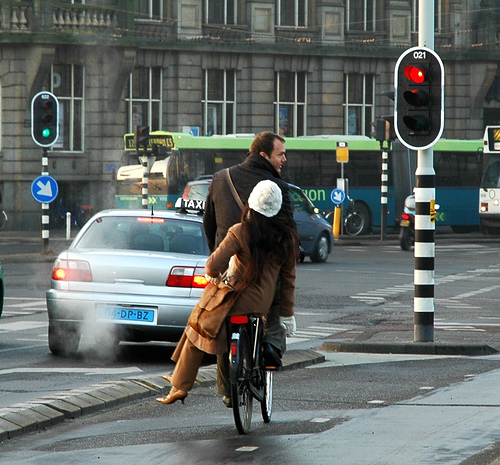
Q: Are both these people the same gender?
A: No, they are both male and female.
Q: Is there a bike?
A: Yes, there is a bike.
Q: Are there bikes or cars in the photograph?
A: Yes, there is a bike.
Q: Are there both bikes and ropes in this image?
A: No, there is a bike but no ropes.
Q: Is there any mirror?
A: No, there are no mirrors.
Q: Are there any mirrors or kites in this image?
A: No, there are no mirrors or kites.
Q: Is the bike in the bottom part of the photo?
A: Yes, the bike is in the bottom of the image.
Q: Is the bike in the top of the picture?
A: No, the bike is in the bottom of the image.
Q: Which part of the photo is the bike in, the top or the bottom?
A: The bike is in the bottom of the image.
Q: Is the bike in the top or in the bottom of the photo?
A: The bike is in the bottom of the image.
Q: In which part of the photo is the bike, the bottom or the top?
A: The bike is in the bottom of the image.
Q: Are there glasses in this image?
A: No, there are no glasses.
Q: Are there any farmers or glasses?
A: No, there are no glasses or farmers.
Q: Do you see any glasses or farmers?
A: No, there are no glasses or farmers.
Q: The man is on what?
A: The man is on the bike.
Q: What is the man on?
A: The man is on the bike.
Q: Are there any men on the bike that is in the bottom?
A: Yes, there is a man on the bike.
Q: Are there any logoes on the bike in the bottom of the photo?
A: No, there is a man on the bike.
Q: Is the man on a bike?
A: Yes, the man is on a bike.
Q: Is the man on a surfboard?
A: No, the man is on a bike.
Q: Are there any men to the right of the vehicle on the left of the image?
A: Yes, there is a man to the right of the car.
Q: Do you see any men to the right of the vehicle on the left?
A: Yes, there is a man to the right of the car.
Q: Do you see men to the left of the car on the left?
A: No, the man is to the right of the car.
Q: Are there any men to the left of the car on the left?
A: No, the man is to the right of the car.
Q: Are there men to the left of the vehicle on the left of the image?
A: No, the man is to the right of the car.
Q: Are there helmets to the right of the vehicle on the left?
A: No, there is a man to the right of the car.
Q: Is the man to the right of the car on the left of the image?
A: Yes, the man is to the right of the car.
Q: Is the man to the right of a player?
A: No, the man is to the right of the car.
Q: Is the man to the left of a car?
A: No, the man is to the right of a car.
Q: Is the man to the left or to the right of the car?
A: The man is to the right of the car.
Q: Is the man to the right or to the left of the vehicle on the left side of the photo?
A: The man is to the right of the car.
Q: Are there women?
A: Yes, there is a woman.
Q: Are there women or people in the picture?
A: Yes, there is a woman.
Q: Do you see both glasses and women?
A: No, there is a woman but no glasses.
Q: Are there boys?
A: No, there are no boys.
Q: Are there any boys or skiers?
A: No, there are no boys or skiers.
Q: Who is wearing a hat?
A: The woman is wearing a hat.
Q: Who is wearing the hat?
A: The woman is wearing a hat.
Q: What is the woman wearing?
A: The woman is wearing a hat.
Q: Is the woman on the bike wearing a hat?
A: Yes, the woman is wearing a hat.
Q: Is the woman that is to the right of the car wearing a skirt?
A: No, the woman is wearing a hat.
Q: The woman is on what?
A: The woman is on the bike.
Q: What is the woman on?
A: The woman is on the bike.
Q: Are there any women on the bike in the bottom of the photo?
A: Yes, there is a woman on the bike.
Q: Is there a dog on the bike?
A: No, there is a woman on the bike.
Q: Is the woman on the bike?
A: Yes, the woman is on the bike.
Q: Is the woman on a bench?
A: No, the woman is on the bike.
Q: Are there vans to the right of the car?
A: No, there is a woman to the right of the car.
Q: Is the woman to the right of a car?
A: Yes, the woman is to the right of a car.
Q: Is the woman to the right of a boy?
A: No, the woman is to the right of a car.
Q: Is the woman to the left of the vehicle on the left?
A: No, the woman is to the right of the car.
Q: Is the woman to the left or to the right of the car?
A: The woman is to the right of the car.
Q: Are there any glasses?
A: No, there are no glasses.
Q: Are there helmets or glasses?
A: No, there are no glasses or helmets.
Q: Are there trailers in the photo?
A: No, there are no trailers.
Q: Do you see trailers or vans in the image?
A: No, there are no trailers or vans.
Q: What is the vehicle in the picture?
A: The vehicle is a car.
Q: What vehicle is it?
A: The vehicle is a car.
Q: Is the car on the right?
A: No, the car is on the left of the image.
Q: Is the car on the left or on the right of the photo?
A: The car is on the left of the image.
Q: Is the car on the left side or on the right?
A: The car is on the left of the image.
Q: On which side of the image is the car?
A: The car is on the left of the image.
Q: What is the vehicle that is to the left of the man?
A: The vehicle is a car.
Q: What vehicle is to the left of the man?
A: The vehicle is a car.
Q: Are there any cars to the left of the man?
A: Yes, there is a car to the left of the man.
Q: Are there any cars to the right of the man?
A: No, the car is to the left of the man.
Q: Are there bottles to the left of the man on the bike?
A: No, there is a car to the left of the man.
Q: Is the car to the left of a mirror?
A: No, the car is to the left of the man.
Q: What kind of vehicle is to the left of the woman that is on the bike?
A: The vehicle is a car.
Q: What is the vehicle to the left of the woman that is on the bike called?
A: The vehicle is a car.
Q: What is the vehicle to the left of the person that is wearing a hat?
A: The vehicle is a car.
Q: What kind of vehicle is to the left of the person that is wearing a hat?
A: The vehicle is a car.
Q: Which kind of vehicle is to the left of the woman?
A: The vehicle is a car.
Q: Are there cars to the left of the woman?
A: Yes, there is a car to the left of the woman.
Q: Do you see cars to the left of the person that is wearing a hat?
A: Yes, there is a car to the left of the woman.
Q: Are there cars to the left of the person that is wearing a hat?
A: Yes, there is a car to the left of the woman.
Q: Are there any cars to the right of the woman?
A: No, the car is to the left of the woman.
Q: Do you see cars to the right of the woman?
A: No, the car is to the left of the woman.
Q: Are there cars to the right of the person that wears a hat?
A: No, the car is to the left of the woman.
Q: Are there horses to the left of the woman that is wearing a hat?
A: No, there is a car to the left of the woman.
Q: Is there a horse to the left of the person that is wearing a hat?
A: No, there is a car to the left of the woman.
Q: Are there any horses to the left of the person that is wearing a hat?
A: No, there is a car to the left of the woman.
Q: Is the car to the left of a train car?
A: No, the car is to the left of the woman.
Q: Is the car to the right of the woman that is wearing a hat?
A: No, the car is to the left of the woman.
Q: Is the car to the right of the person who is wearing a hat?
A: No, the car is to the left of the woman.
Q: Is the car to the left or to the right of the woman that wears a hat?
A: The car is to the left of the woman.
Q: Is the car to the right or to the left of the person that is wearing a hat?
A: The car is to the left of the woman.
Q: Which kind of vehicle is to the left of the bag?
A: The vehicle is a car.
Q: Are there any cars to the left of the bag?
A: Yes, there is a car to the left of the bag.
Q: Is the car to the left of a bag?
A: Yes, the car is to the left of a bag.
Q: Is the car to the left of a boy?
A: No, the car is to the left of a bag.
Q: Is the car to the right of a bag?
A: No, the car is to the left of a bag.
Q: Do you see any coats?
A: Yes, there is a coat.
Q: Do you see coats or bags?
A: Yes, there is a coat.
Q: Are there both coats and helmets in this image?
A: No, there is a coat but no helmets.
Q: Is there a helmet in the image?
A: No, there are no helmets.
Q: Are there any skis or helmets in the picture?
A: No, there are no helmets or skis.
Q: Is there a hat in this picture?
A: Yes, there is a hat.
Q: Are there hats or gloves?
A: Yes, there is a hat.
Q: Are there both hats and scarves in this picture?
A: No, there is a hat but no scarves.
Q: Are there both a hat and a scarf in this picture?
A: No, there is a hat but no scarves.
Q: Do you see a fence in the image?
A: No, there are no fences.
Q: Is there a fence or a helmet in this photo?
A: No, there are no fences or helmets.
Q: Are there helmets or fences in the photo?
A: No, there are no fences or helmets.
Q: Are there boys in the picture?
A: No, there are no boys.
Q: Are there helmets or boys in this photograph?
A: No, there are no boys or helmets.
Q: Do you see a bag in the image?
A: Yes, there is a bag.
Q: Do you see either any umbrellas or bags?
A: Yes, there is a bag.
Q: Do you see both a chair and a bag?
A: No, there is a bag but no chairs.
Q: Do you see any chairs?
A: No, there are no chairs.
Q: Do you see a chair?
A: No, there are no chairs.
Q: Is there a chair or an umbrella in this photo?
A: No, there are no chairs or umbrellas.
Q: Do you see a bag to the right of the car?
A: Yes, there is a bag to the right of the car.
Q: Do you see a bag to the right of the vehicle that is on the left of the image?
A: Yes, there is a bag to the right of the car.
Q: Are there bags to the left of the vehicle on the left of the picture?
A: No, the bag is to the right of the car.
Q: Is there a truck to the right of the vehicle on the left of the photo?
A: No, there is a bag to the right of the car.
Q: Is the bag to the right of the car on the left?
A: Yes, the bag is to the right of the car.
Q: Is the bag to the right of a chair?
A: No, the bag is to the right of the car.